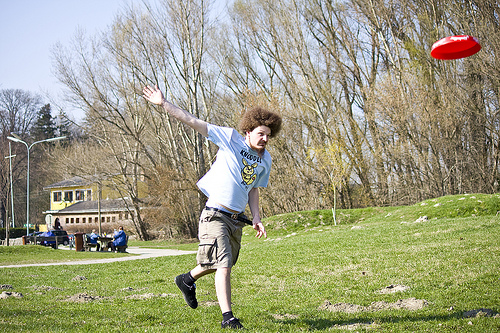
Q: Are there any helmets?
A: No, there are no helmets.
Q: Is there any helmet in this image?
A: No, there are no helmets.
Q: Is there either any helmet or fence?
A: No, there are no helmets or fences.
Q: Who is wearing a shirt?
A: The man is wearing a shirt.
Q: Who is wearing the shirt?
A: The man is wearing a shirt.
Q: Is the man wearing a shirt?
A: Yes, the man is wearing a shirt.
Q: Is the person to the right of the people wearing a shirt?
A: Yes, the man is wearing a shirt.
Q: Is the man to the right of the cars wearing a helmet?
A: No, the man is wearing a shirt.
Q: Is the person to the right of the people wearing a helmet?
A: No, the man is wearing a shirt.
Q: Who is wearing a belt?
A: The man is wearing a belt.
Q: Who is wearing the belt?
A: The man is wearing a belt.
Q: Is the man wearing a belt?
A: Yes, the man is wearing a belt.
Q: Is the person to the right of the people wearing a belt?
A: Yes, the man is wearing a belt.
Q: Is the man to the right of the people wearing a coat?
A: No, the man is wearing a belt.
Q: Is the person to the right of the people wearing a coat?
A: No, the man is wearing a belt.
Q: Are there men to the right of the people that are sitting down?
A: Yes, there is a man to the right of the people.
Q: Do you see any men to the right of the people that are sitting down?
A: Yes, there is a man to the right of the people.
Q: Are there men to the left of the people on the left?
A: No, the man is to the right of the people.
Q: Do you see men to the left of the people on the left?
A: No, the man is to the right of the people.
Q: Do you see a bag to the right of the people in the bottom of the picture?
A: No, there is a man to the right of the people.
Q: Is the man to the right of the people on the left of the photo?
A: Yes, the man is to the right of the people.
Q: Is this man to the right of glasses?
A: No, the man is to the right of the people.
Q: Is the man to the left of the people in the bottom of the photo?
A: No, the man is to the right of the people.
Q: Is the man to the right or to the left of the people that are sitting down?
A: The man is to the right of the people.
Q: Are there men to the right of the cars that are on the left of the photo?
A: Yes, there is a man to the right of the cars.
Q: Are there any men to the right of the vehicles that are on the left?
A: Yes, there is a man to the right of the cars.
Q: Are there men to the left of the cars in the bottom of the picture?
A: No, the man is to the right of the cars.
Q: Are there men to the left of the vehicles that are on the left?
A: No, the man is to the right of the cars.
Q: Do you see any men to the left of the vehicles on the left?
A: No, the man is to the right of the cars.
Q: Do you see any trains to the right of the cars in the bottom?
A: No, there is a man to the right of the cars.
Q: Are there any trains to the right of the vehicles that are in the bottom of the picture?
A: No, there is a man to the right of the cars.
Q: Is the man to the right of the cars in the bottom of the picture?
A: Yes, the man is to the right of the cars.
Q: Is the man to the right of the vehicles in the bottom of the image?
A: Yes, the man is to the right of the cars.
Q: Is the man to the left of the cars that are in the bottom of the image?
A: No, the man is to the right of the cars.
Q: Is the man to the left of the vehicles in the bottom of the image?
A: No, the man is to the right of the cars.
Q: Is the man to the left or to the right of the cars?
A: The man is to the right of the cars.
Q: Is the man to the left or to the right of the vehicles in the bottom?
A: The man is to the right of the cars.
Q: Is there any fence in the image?
A: No, there are no fences.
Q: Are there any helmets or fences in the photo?
A: No, there are no fences or helmets.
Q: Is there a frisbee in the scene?
A: Yes, there is a frisbee.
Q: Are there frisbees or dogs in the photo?
A: Yes, there is a frisbee.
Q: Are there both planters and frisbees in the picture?
A: No, there is a frisbee but no planters.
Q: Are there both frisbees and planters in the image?
A: No, there is a frisbee but no planters.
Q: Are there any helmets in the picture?
A: No, there are no helmets.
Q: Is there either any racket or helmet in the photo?
A: No, there are no helmets or rackets.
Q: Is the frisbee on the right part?
A: Yes, the frisbee is on the right of the image.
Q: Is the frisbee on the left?
A: No, the frisbee is on the right of the image.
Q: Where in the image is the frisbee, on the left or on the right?
A: The frisbee is on the right of the image.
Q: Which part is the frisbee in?
A: The frisbee is on the right of the image.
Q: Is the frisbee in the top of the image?
A: Yes, the frisbee is in the top of the image.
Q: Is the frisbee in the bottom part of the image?
A: No, the frisbee is in the top of the image.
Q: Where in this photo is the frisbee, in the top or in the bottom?
A: The frisbee is in the top of the image.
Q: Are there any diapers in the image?
A: No, there are no diapers.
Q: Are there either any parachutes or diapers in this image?
A: No, there are no diapers or parachutes.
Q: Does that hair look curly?
A: Yes, the hair is curly.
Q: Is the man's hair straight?
A: No, the hair is curly.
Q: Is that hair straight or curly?
A: The hair is curly.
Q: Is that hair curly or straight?
A: The hair is curly.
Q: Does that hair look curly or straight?
A: The hair is curly.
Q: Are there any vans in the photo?
A: No, there are no vans.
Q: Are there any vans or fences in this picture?
A: No, there are no vans or fences.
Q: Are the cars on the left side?
A: Yes, the cars are on the left of the image.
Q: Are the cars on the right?
A: No, the cars are on the left of the image.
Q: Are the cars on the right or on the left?
A: The cars are on the left of the image.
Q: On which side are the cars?
A: The cars are on the left of the image.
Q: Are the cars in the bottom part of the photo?
A: Yes, the cars are in the bottom of the image.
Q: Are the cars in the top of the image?
A: No, the cars are in the bottom of the image.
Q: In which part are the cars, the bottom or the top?
A: The cars are in the bottom of the image.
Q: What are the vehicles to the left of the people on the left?
A: The vehicles are cars.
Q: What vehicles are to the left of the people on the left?
A: The vehicles are cars.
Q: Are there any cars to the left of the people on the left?
A: Yes, there are cars to the left of the people.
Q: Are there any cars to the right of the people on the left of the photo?
A: No, the cars are to the left of the people.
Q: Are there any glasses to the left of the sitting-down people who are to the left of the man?
A: No, there are cars to the left of the people.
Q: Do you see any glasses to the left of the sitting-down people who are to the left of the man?
A: No, there are cars to the left of the people.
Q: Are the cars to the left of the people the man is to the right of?
A: Yes, the cars are to the left of the people.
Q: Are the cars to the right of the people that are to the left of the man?
A: No, the cars are to the left of the people.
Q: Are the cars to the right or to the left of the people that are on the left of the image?
A: The cars are to the left of the people.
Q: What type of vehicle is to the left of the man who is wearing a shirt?
A: The vehicles are cars.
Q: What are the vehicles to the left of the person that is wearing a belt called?
A: The vehicles are cars.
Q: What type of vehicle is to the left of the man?
A: The vehicles are cars.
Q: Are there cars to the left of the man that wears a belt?
A: Yes, there are cars to the left of the man.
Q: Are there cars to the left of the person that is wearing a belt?
A: Yes, there are cars to the left of the man.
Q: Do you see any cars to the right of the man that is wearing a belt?
A: No, the cars are to the left of the man.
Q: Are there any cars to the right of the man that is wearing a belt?
A: No, the cars are to the left of the man.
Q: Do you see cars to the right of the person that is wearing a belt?
A: No, the cars are to the left of the man.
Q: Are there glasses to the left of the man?
A: No, there are cars to the left of the man.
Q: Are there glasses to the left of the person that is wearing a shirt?
A: No, there are cars to the left of the man.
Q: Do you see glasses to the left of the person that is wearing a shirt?
A: No, there are cars to the left of the man.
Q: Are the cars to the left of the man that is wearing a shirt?
A: Yes, the cars are to the left of the man.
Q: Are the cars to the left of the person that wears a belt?
A: Yes, the cars are to the left of the man.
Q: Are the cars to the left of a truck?
A: No, the cars are to the left of the man.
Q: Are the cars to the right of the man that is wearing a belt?
A: No, the cars are to the left of the man.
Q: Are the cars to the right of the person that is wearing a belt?
A: No, the cars are to the left of the man.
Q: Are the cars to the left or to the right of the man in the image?
A: The cars are to the left of the man.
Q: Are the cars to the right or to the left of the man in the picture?
A: The cars are to the left of the man.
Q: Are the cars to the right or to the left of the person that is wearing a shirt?
A: The cars are to the left of the man.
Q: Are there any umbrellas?
A: No, there are no umbrellas.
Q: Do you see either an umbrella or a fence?
A: No, there are no umbrellas or fences.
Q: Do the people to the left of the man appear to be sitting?
A: Yes, the people are sitting.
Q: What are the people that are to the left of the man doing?
A: The people are sitting.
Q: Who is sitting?
A: The people are sitting.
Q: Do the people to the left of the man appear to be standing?
A: No, the people are sitting.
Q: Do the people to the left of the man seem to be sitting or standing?
A: The people are sitting.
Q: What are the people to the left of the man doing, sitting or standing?
A: The people are sitting.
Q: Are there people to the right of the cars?
A: Yes, there are people to the right of the cars.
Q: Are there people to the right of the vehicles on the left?
A: Yes, there are people to the right of the cars.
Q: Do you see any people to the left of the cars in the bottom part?
A: No, the people are to the right of the cars.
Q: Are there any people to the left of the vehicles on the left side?
A: No, the people are to the right of the cars.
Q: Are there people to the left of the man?
A: Yes, there are people to the left of the man.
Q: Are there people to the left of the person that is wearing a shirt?
A: Yes, there are people to the left of the man.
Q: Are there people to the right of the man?
A: No, the people are to the left of the man.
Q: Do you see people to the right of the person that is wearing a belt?
A: No, the people are to the left of the man.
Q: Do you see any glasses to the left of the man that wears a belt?
A: No, there are people to the left of the man.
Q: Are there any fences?
A: No, there are no fences.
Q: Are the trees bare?
A: Yes, the trees are bare.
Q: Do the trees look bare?
A: Yes, the trees are bare.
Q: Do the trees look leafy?
A: No, the trees are bare.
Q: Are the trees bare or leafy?
A: The trees are bare.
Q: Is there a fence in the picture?
A: No, there are no fences.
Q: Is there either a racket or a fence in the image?
A: No, there are no fences or rackets.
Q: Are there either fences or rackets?
A: No, there are no fences or rackets.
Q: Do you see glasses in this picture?
A: No, there are no glasses.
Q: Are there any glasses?
A: No, there are no glasses.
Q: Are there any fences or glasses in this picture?
A: No, there are no glasses or fences.